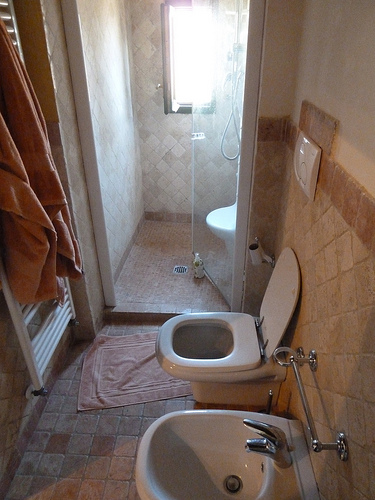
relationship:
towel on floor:
[90, 330, 182, 426] [65, 434, 117, 485]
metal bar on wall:
[272, 354, 330, 453] [314, 53, 350, 95]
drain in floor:
[169, 255, 204, 293] [65, 434, 117, 485]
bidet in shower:
[210, 199, 239, 244] [84, 21, 261, 309]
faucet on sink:
[236, 419, 298, 484] [134, 404, 328, 493]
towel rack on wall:
[3, 11, 28, 47] [314, 53, 350, 95]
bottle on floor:
[189, 236, 211, 309] [65, 434, 117, 485]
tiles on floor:
[45, 418, 114, 432] [65, 434, 117, 485]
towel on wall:
[90, 330, 182, 426] [314, 53, 350, 95]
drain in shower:
[169, 255, 204, 293] [84, 21, 261, 309]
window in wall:
[156, 8, 267, 119] [314, 53, 350, 95]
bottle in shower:
[189, 236, 211, 309] [84, 21, 261, 309]